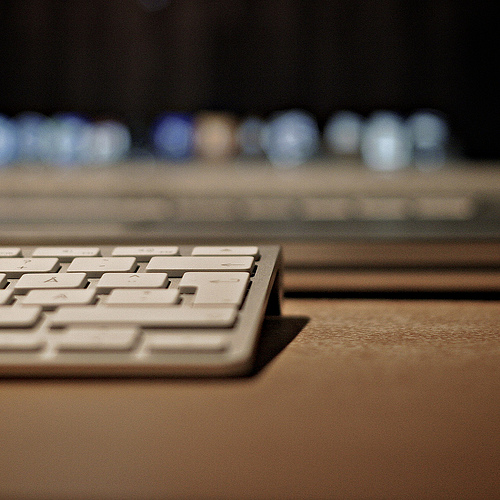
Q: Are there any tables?
A: Yes, there is a table.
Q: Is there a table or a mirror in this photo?
A: Yes, there is a table.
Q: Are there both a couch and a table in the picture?
A: No, there is a table but no couches.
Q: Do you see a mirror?
A: No, there are no mirrors.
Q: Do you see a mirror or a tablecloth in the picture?
A: No, there are no mirrors or tablecloths.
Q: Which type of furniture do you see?
A: The furniture is a table.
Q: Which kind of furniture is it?
A: The piece of furniture is a table.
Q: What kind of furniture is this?
A: That is a table.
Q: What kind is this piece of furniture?
A: That is a table.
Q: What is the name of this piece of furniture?
A: That is a table.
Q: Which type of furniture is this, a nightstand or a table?
A: That is a table.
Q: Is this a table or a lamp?
A: This is a table.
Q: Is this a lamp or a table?
A: This is a table.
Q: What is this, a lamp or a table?
A: This is a table.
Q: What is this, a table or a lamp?
A: This is a table.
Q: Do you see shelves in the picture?
A: No, there are no shelves.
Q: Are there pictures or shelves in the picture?
A: No, there are no shelves or pictures.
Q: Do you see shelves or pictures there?
A: No, there are no shelves or pictures.